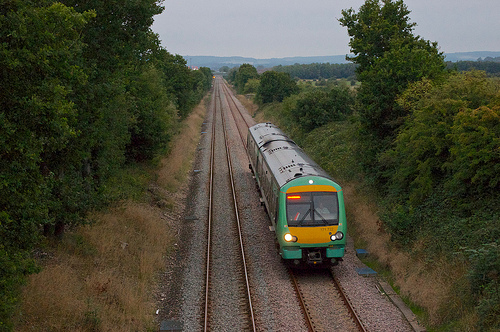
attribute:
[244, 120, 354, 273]
train — green, yellow, short, large, moving, in motion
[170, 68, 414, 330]
rail road tracks — large, narrow, long, rusty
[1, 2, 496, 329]
bushes — dark, large, tall, green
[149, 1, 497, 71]
sky — blue, foggy, cloudy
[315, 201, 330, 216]
person — conductor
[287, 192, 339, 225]
windshield — square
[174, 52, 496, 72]
mountains — large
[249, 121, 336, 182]
roof — grey